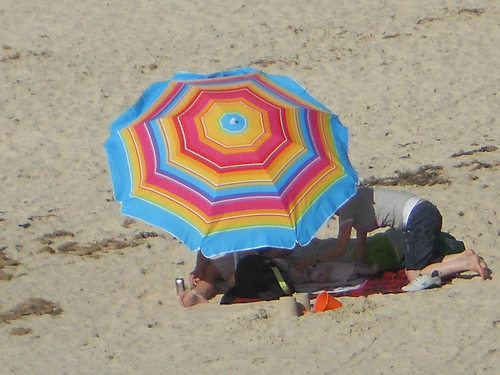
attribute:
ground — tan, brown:
[1, 1, 499, 365]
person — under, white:
[293, 171, 493, 281]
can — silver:
[169, 275, 192, 296]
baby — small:
[286, 252, 376, 282]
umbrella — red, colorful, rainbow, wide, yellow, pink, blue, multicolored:
[105, 66, 358, 256]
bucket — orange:
[314, 290, 341, 311]